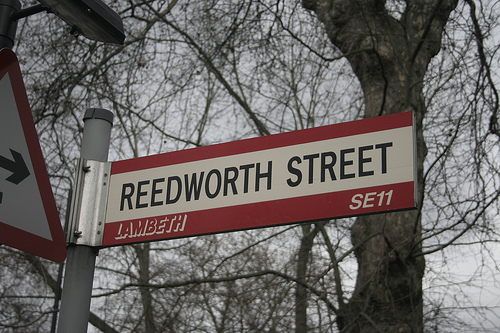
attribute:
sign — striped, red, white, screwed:
[75, 107, 455, 251]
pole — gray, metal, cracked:
[59, 99, 118, 332]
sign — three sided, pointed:
[0, 41, 80, 266]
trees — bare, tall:
[1, 1, 499, 331]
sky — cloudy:
[49, 28, 499, 265]